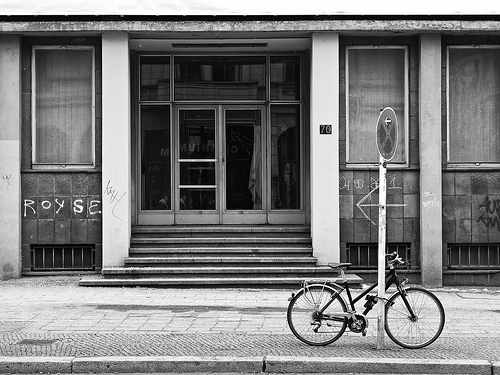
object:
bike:
[286, 250, 446, 352]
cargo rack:
[297, 277, 346, 285]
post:
[376, 164, 389, 352]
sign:
[373, 106, 399, 162]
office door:
[219, 105, 268, 227]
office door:
[174, 102, 223, 226]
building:
[0, 21, 498, 290]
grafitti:
[23, 196, 105, 216]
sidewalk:
[3, 284, 499, 363]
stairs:
[130, 224, 311, 249]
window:
[28, 44, 97, 166]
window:
[343, 44, 409, 165]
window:
[443, 42, 499, 163]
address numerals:
[320, 125, 332, 135]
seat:
[328, 262, 352, 269]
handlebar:
[386, 251, 397, 262]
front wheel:
[383, 286, 448, 351]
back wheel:
[285, 284, 348, 346]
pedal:
[347, 310, 358, 324]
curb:
[2, 350, 494, 374]